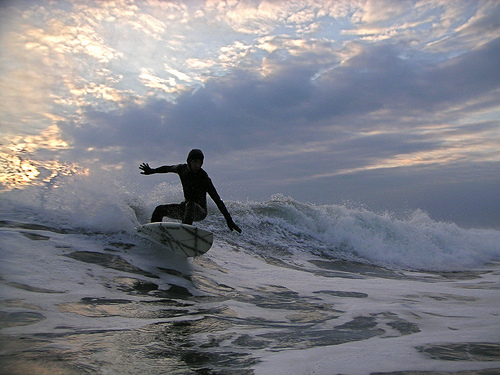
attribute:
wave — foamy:
[0, 156, 498, 270]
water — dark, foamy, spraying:
[1, 162, 499, 373]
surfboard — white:
[136, 222, 214, 258]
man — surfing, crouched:
[140, 148, 243, 232]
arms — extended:
[138, 161, 242, 233]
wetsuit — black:
[140, 149, 244, 233]